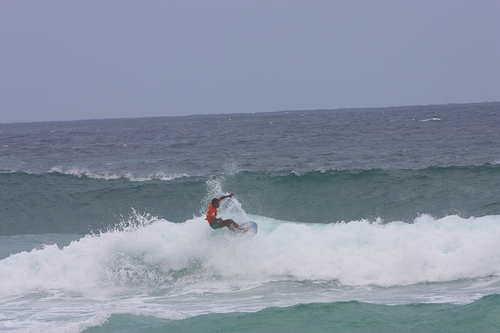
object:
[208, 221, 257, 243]
board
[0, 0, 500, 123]
clouds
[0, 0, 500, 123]
sky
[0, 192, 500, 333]
wave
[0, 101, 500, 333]
water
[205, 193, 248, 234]
man